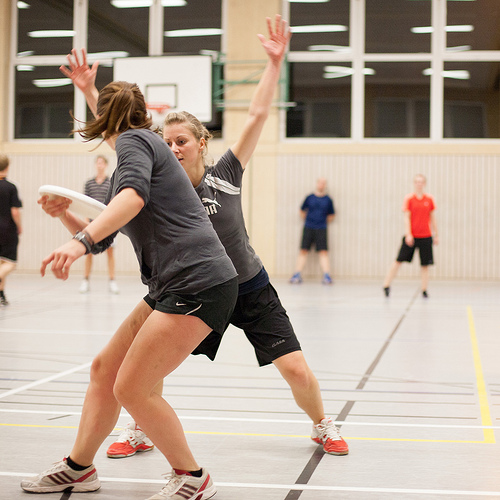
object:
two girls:
[16, 13, 350, 499]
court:
[0, 0, 499, 498]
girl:
[16, 80, 240, 499]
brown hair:
[67, 79, 161, 153]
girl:
[58, 13, 349, 458]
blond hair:
[152, 111, 218, 173]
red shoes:
[310, 415, 350, 454]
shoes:
[143, 466, 217, 499]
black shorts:
[142, 275, 238, 345]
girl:
[382, 172, 439, 298]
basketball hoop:
[112, 55, 213, 130]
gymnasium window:
[285, 0, 352, 140]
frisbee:
[37, 185, 113, 222]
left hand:
[40, 238, 88, 280]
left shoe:
[18, 455, 100, 495]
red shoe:
[106, 421, 155, 458]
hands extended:
[59, 12, 292, 175]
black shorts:
[190, 265, 301, 366]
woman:
[0, 152, 24, 306]